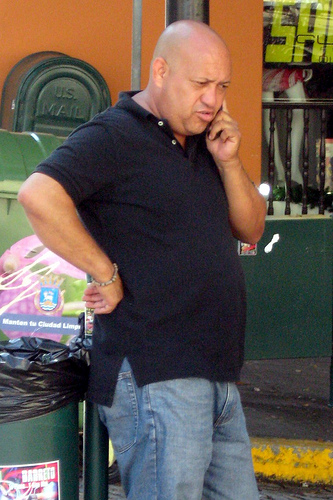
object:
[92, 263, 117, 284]
wrist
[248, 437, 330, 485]
curb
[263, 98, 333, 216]
fence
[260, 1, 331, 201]
window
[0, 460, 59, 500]
sign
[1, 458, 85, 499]
sticker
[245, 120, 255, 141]
ground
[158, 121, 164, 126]
button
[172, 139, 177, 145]
button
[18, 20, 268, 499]
man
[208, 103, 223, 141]
phone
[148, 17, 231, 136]
head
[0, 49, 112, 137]
mailbox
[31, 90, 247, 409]
shirt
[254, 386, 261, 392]
pebbles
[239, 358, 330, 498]
ground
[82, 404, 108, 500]
green pole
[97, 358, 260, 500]
blue jeans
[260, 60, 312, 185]
mannequin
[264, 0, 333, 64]
lettering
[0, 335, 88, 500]
garbage can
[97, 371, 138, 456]
pocket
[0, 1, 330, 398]
building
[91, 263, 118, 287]
bracelet